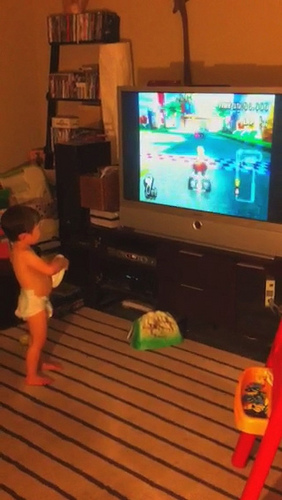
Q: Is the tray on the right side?
A: Yes, the tray is on the right of the image.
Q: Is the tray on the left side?
A: No, the tray is on the right of the image.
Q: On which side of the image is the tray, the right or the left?
A: The tray is on the right of the image.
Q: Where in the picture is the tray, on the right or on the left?
A: The tray is on the right of the image.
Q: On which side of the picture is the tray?
A: The tray is on the right of the image.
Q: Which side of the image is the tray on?
A: The tray is on the right of the image.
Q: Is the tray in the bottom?
A: Yes, the tray is in the bottom of the image.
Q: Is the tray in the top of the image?
A: No, the tray is in the bottom of the image.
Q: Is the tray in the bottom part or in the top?
A: The tray is in the bottom of the image.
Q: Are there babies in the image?
A: Yes, there is a baby.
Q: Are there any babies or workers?
A: Yes, there is a baby.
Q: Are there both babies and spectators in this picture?
A: No, there is a baby but no spectators.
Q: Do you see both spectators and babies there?
A: No, there is a baby but no spectators.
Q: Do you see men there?
A: No, there are no men.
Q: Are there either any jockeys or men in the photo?
A: No, there are no men or jockeys.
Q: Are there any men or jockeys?
A: No, there are no men or jockeys.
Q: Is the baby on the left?
A: Yes, the baby is on the left of the image.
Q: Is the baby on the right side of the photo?
A: No, the baby is on the left of the image.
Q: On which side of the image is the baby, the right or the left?
A: The baby is on the left of the image.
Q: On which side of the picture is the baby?
A: The baby is on the left of the image.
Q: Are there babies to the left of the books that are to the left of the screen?
A: Yes, there is a baby to the left of the books.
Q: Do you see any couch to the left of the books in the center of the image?
A: No, there is a baby to the left of the books.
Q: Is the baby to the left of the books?
A: Yes, the baby is to the left of the books.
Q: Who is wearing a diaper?
A: The baby is wearing a diaper.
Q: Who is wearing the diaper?
A: The baby is wearing a diaper.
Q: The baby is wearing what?
A: The baby is wearing a diaper.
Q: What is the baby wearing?
A: The baby is wearing a diaper.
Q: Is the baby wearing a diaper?
A: Yes, the baby is wearing a diaper.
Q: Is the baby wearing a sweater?
A: No, the baby is wearing a diaper.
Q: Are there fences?
A: No, there are no fences.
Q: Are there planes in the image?
A: No, there are no planes.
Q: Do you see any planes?
A: No, there are no planes.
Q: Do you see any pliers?
A: No, there are no pliers.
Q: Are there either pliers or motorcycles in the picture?
A: No, there are no pliers or motorcycles.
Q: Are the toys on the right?
A: Yes, the toys are on the right of the image.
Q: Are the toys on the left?
A: No, the toys are on the right of the image.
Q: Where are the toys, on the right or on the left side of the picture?
A: The toys are on the right of the image.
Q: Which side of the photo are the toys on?
A: The toys are on the right of the image.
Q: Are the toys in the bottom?
A: Yes, the toys are in the bottom of the image.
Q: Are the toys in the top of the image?
A: No, the toys are in the bottom of the image.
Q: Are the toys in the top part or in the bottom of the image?
A: The toys are in the bottom of the image.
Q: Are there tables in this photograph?
A: No, there are no tables.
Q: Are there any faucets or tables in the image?
A: No, there are no tables or faucets.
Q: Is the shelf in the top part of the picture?
A: Yes, the shelf is in the top of the image.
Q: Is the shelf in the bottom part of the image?
A: No, the shelf is in the top of the image.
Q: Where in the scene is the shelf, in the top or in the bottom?
A: The shelf is in the top of the image.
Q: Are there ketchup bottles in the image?
A: No, there are no ketchup bottles.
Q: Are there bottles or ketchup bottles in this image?
A: No, there are no ketchup bottles or bottles.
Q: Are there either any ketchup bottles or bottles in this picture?
A: No, there are no ketchup bottles or bottles.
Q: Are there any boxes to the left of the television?
A: Yes, there is a box to the left of the television.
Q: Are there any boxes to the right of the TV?
A: No, the box is to the left of the TV.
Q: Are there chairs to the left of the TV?
A: No, there is a box to the left of the TV.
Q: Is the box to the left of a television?
A: Yes, the box is to the left of a television.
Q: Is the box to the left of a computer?
A: No, the box is to the left of a television.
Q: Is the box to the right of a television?
A: No, the box is to the left of a television.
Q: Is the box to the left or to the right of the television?
A: The box is to the left of the television.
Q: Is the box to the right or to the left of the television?
A: The box is to the left of the television.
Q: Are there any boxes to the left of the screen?
A: Yes, there is a box to the left of the screen.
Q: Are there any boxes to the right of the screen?
A: No, the box is to the left of the screen.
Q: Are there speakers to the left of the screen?
A: No, there is a box to the left of the screen.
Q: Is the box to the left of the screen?
A: Yes, the box is to the left of the screen.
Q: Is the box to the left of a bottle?
A: No, the box is to the left of the screen.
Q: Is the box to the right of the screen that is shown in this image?
A: No, the box is to the left of the screen.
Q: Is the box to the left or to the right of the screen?
A: The box is to the left of the screen.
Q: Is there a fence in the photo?
A: No, there are no fences.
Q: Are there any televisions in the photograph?
A: Yes, there is a television.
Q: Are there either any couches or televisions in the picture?
A: Yes, there is a television.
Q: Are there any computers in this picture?
A: No, there are no computers.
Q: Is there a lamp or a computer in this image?
A: No, there are no computers or lamps.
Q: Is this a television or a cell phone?
A: This is a television.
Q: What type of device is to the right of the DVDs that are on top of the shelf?
A: The device is a television.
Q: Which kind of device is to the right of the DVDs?
A: The device is a television.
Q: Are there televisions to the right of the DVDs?
A: Yes, there is a television to the right of the DVDs.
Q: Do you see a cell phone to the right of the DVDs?
A: No, there is a television to the right of the DVDs.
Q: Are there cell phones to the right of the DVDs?
A: No, there is a television to the right of the DVDs.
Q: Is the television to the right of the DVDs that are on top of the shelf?
A: Yes, the television is to the right of the DVDs.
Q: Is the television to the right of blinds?
A: No, the television is to the right of the DVDs.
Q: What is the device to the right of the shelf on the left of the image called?
A: The device is a television.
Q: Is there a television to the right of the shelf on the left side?
A: Yes, there is a television to the right of the shelf.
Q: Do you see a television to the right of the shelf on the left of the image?
A: Yes, there is a television to the right of the shelf.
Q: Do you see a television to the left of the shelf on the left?
A: No, the television is to the right of the shelf.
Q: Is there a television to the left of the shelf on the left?
A: No, the television is to the right of the shelf.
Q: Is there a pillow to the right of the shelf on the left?
A: No, there is a television to the right of the shelf.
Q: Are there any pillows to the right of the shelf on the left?
A: No, there is a television to the right of the shelf.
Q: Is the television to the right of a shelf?
A: Yes, the television is to the right of a shelf.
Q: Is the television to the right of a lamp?
A: No, the television is to the right of a shelf.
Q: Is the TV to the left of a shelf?
A: No, the TV is to the right of a shelf.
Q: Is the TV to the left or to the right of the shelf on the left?
A: The TV is to the right of the shelf.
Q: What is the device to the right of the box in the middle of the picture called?
A: The device is a television.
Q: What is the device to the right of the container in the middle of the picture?
A: The device is a television.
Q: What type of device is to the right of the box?
A: The device is a television.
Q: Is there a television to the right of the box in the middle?
A: Yes, there is a television to the right of the box.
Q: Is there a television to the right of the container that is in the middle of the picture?
A: Yes, there is a television to the right of the box.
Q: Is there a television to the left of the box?
A: No, the television is to the right of the box.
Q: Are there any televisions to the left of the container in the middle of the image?
A: No, the television is to the right of the box.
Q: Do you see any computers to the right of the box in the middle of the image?
A: No, there is a television to the right of the box.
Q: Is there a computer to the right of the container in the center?
A: No, there is a television to the right of the box.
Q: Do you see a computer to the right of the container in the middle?
A: No, there is a television to the right of the box.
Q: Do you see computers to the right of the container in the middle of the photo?
A: No, there is a television to the right of the box.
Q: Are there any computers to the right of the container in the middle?
A: No, there is a television to the right of the box.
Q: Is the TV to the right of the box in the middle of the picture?
A: Yes, the TV is to the right of the box.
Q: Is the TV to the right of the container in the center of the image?
A: Yes, the TV is to the right of the box.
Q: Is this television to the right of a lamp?
A: No, the television is to the right of the box.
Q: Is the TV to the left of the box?
A: No, the TV is to the right of the box.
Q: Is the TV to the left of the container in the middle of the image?
A: No, the TV is to the right of the box.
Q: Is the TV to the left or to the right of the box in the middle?
A: The TV is to the right of the box.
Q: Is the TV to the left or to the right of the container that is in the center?
A: The TV is to the right of the box.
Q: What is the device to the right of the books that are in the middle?
A: The device is a television.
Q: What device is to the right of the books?
A: The device is a television.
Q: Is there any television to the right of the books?
A: Yes, there is a television to the right of the books.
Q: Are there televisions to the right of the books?
A: Yes, there is a television to the right of the books.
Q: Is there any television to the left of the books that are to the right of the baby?
A: No, the television is to the right of the books.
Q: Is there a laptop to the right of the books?
A: No, there is a television to the right of the books.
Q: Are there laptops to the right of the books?
A: No, there is a television to the right of the books.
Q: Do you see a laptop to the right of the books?
A: No, there is a television to the right of the books.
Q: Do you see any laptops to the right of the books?
A: No, there is a television to the right of the books.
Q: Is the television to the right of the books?
A: Yes, the television is to the right of the books.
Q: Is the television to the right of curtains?
A: No, the television is to the right of the books.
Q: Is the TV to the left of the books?
A: No, the TV is to the right of the books.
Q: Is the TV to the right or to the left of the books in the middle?
A: The TV is to the right of the books.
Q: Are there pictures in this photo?
A: No, there are no pictures.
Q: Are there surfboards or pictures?
A: No, there are no pictures or surfboards.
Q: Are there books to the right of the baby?
A: Yes, there are books to the right of the baby.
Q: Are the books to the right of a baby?
A: Yes, the books are to the right of a baby.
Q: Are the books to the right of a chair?
A: No, the books are to the right of a baby.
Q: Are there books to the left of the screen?
A: Yes, there are books to the left of the screen.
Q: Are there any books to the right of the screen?
A: No, the books are to the left of the screen.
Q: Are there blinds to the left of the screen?
A: No, there are books to the left of the screen.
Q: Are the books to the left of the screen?
A: Yes, the books are to the left of the screen.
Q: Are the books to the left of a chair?
A: No, the books are to the left of the screen.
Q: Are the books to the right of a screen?
A: No, the books are to the left of a screen.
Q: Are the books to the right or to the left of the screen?
A: The books are to the left of the screen.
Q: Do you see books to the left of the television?
A: Yes, there are books to the left of the television.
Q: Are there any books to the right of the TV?
A: No, the books are to the left of the TV.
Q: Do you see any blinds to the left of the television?
A: No, there are books to the left of the television.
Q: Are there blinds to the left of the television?
A: No, there are books to the left of the television.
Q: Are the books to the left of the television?
A: Yes, the books are to the left of the television.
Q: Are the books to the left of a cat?
A: No, the books are to the left of the television.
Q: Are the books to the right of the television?
A: No, the books are to the left of the television.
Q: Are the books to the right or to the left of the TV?
A: The books are to the left of the TV.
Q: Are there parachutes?
A: No, there are no parachutes.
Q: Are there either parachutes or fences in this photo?
A: No, there are no parachutes or fences.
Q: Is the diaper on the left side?
A: Yes, the diaper is on the left of the image.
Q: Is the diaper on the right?
A: No, the diaper is on the left of the image.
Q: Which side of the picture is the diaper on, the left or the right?
A: The diaper is on the left of the image.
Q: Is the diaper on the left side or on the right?
A: The diaper is on the left of the image.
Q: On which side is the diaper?
A: The diaper is on the left of the image.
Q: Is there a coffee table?
A: No, there are no coffee tables.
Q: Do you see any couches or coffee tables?
A: No, there are no coffee tables or couches.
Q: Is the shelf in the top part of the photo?
A: Yes, the shelf is in the top of the image.